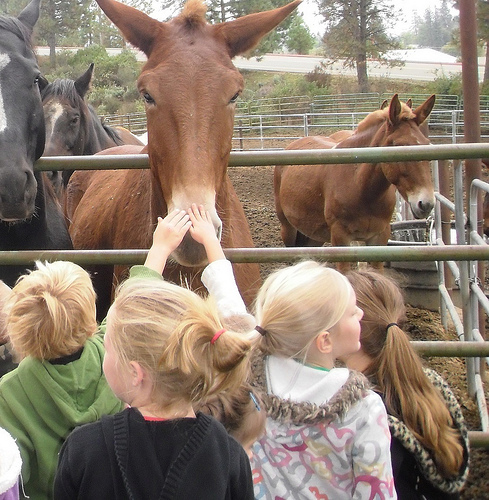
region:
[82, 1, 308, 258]
Head of a mule and two hands.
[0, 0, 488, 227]
Equine within a metal fence.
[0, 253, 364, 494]
Three blonde haired children.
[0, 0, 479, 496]
Children looking at horses and mules.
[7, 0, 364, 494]
Two children petting a mule.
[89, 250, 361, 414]
Two blonde haired girls with ponytails.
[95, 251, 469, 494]
Three girls with ponytails in front of a fence.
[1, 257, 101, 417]
Blonde haired boy with green hoodie.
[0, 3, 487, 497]
Children observing animals on a farm.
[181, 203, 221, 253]
a childs hand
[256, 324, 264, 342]
a brown hair tie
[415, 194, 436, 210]
the horses nose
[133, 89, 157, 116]
the right eye of the horse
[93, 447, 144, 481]
a black sweater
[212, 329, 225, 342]
a pink hair tie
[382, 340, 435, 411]
a ponytail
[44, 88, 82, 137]
a black horse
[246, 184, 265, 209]
the dirt is black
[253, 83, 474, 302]
brown horse in pen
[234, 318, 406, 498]
little girl wearing white colorful hoodie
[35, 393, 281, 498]
little girl wearing a black hoodie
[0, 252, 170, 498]
child wearing a green hoodie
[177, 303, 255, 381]
little girl wearing pink hair tie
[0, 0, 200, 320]
black horses in pen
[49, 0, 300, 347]
brown horse in pen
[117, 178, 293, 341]
kids touching horses nose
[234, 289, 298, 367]
little girl wearing a purple tie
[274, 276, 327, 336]
the hair is blonde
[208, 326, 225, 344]
the hair tie is pink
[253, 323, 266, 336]
the hair tie is purple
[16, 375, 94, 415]
the sweatshirt is green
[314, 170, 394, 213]
the horse is brown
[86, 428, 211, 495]
the sweatshirt is black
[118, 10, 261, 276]
the horse is being pet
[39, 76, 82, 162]
the horse is black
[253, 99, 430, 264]
the horse is in the pen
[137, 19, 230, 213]
the horse is brown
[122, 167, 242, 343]
children petting the horse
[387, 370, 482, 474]
her coat is fur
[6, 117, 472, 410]
the horses are caged in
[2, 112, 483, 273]
the cage is metal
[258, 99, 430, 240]
The horse is brown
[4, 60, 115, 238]
The horses are black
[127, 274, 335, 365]
They have blond hair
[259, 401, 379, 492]
Her coat has hearts on it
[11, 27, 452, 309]
Four horses in the cage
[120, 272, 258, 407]
the hair is blonde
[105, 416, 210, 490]
the sweater is black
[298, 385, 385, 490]
the jacket is white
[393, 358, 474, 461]
the hair is brown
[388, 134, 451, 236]
the horse is brown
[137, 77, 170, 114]
left eye of the horse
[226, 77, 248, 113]
the right eye of the horse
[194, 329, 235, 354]
the bow is red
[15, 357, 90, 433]
the sweater is green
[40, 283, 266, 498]
girl with a black hooded sweater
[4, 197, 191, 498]
child with a green jacket